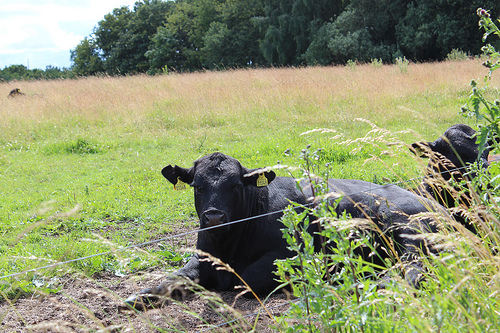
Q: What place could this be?
A: It is a pasture.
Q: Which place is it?
A: It is a pasture.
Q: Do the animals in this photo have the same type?
A: Yes, all the animals are cows.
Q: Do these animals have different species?
A: No, all the animals are cows.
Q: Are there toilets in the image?
A: No, there are no toilets.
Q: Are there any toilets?
A: No, there are no toilets.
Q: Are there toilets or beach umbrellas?
A: No, there are no toilets or beach umbrellas.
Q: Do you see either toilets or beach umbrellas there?
A: No, there are no toilets or beach umbrellas.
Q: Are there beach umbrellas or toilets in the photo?
A: No, there are no toilets or beach umbrellas.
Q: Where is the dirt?
A: The dirt is in the pasture.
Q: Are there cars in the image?
A: No, there are no cars.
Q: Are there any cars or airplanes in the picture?
A: No, there are no cars or airplanes.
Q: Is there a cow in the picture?
A: Yes, there is a cow.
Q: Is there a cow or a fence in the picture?
A: Yes, there is a cow.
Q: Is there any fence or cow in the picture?
A: Yes, there is a cow.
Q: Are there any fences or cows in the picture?
A: Yes, there is a cow.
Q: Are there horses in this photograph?
A: No, there are no horses.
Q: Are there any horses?
A: No, there are no horses.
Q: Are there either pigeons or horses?
A: No, there are no horses or pigeons.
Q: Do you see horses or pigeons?
A: No, there are no horses or pigeons.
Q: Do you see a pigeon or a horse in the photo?
A: No, there are no horses or pigeons.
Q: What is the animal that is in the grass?
A: The animal is a cow.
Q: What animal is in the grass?
A: The animal is a cow.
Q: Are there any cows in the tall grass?
A: Yes, there is a cow in the grass.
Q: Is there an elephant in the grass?
A: No, there is a cow in the grass.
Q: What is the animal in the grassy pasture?
A: The animal is a cow.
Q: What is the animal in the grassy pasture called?
A: The animal is a cow.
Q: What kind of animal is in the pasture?
A: The animal is a cow.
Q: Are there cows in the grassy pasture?
A: Yes, there is a cow in the pasture.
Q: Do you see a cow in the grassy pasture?
A: Yes, there is a cow in the pasture.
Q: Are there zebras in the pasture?
A: No, there is a cow in the pasture.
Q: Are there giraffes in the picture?
A: No, there are no giraffes.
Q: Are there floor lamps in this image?
A: No, there are no floor lamps.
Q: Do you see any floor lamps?
A: No, there are no floor lamps.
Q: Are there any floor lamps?
A: No, there are no floor lamps.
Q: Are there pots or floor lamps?
A: No, there are no floor lamps or pots.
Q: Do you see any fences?
A: Yes, there is a fence.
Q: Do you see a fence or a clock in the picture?
A: Yes, there is a fence.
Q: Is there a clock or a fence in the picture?
A: Yes, there is a fence.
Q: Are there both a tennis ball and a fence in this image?
A: No, there is a fence but no tennis balls.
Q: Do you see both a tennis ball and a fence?
A: No, there is a fence but no tennis balls.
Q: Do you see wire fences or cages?
A: Yes, there is a wire fence.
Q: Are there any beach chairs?
A: No, there are no beach chairs.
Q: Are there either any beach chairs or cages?
A: No, there are no beach chairs or cages.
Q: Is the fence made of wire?
A: Yes, the fence is made of wire.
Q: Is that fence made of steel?
A: No, the fence is made of wire.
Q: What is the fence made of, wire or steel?
A: The fence is made of wire.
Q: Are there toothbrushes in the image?
A: No, there are no toothbrushes.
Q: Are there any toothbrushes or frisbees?
A: No, there are no toothbrushes or frisbees.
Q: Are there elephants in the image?
A: No, there are no elephants.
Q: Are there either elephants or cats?
A: No, there are no elephants or cats.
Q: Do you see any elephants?
A: No, there are no elephants.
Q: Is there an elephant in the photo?
A: No, there are no elephants.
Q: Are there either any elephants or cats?
A: No, there are no elephants or cats.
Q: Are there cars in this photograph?
A: No, there are no cars.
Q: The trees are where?
A: The trees are in the pasture.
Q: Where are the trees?
A: The trees are in the pasture.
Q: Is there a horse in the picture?
A: No, there are no horses.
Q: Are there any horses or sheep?
A: No, there are no horses or sheep.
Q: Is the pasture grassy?
A: Yes, the pasture is grassy.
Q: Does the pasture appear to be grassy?
A: Yes, the pasture is grassy.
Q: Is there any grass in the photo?
A: Yes, there is grass.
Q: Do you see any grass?
A: Yes, there is grass.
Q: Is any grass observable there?
A: Yes, there is grass.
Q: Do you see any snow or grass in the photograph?
A: Yes, there is grass.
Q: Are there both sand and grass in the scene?
A: No, there is grass but no sand.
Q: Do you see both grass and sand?
A: No, there is grass but no sand.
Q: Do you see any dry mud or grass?
A: Yes, there is dry grass.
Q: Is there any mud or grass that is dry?
A: Yes, the grass is dry.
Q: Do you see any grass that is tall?
A: Yes, there is tall grass.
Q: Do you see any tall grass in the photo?
A: Yes, there is tall grass.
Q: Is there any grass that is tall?
A: Yes, there is grass that is tall.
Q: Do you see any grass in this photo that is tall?
A: Yes, there is grass that is tall.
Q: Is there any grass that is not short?
A: Yes, there is tall grass.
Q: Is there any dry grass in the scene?
A: Yes, there is dry grass.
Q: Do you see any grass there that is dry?
A: Yes, there is grass that is dry.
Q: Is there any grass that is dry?
A: Yes, there is grass that is dry.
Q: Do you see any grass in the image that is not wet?
A: Yes, there is dry grass.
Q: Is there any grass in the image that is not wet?
A: Yes, there is dry grass.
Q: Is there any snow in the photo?
A: No, there is no snow.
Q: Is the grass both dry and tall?
A: Yes, the grass is dry and tall.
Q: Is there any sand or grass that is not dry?
A: No, there is grass but it is dry.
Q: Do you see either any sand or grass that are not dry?
A: No, there is grass but it is dry.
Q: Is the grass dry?
A: Yes, the grass is dry.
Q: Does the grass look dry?
A: Yes, the grass is dry.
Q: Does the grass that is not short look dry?
A: Yes, the grass is dry.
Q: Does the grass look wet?
A: No, the grass is dry.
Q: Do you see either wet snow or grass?
A: No, there is grass but it is dry.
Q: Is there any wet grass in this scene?
A: No, there is grass but it is dry.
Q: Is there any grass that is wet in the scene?
A: No, there is grass but it is dry.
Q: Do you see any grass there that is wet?
A: No, there is grass but it is dry.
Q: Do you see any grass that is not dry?
A: No, there is grass but it is dry.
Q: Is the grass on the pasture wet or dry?
A: The grass is dry.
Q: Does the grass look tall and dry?
A: Yes, the grass is tall and dry.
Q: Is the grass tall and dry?
A: Yes, the grass is tall and dry.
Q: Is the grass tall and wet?
A: No, the grass is tall but dry.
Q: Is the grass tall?
A: Yes, the grass is tall.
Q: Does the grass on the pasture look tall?
A: Yes, the grass is tall.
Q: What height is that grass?
A: The grass is tall.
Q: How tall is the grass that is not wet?
A: The grass is tall.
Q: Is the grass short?
A: No, the grass is tall.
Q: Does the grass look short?
A: No, the grass is tall.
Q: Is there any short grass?
A: No, there is grass but it is tall.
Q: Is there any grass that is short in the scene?
A: No, there is grass but it is tall.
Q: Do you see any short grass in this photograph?
A: No, there is grass but it is tall.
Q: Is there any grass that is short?
A: No, there is grass but it is tall.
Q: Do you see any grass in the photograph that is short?
A: No, there is grass but it is tall.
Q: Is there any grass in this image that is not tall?
A: No, there is grass but it is tall.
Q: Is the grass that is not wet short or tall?
A: The grass is tall.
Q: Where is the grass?
A: The grass is on the pasture.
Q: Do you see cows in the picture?
A: Yes, there is a cow.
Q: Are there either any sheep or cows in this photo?
A: Yes, there is a cow.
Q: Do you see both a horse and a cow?
A: No, there is a cow but no horses.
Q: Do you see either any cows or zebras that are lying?
A: Yes, the cow is lying.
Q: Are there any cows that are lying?
A: Yes, there is a cow that is lying.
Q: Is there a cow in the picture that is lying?
A: Yes, there is a cow that is lying.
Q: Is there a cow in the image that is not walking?
A: Yes, there is a cow that is lying.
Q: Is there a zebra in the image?
A: No, there are no zebras.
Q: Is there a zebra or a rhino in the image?
A: No, there are no zebras or rhinos.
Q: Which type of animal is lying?
A: The animal is a cow.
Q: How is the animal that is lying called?
A: The animal is a cow.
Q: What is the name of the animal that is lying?
A: The animal is a cow.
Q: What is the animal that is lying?
A: The animal is a cow.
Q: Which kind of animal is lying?
A: The animal is a cow.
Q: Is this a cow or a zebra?
A: This is a cow.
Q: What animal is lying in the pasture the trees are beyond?
A: The cow is lying in the pasture.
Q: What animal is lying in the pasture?
A: The cow is lying in the pasture.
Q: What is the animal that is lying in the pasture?
A: The animal is a cow.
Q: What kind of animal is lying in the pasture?
A: The animal is a cow.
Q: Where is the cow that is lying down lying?
A: The cow is lying in the pasture.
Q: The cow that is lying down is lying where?
A: The cow is lying in the pasture.